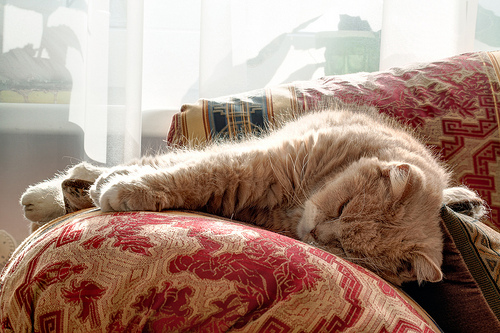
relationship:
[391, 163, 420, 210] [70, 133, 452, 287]
ear of cat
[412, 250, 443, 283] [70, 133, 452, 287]
left ear cat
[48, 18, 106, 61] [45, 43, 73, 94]
window has sunlight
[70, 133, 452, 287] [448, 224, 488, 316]
cat sleeping on pillow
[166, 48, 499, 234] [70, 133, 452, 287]
cushion has cat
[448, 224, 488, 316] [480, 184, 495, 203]
pillow in corner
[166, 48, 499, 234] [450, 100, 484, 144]
cushion has pattern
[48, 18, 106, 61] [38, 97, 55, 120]
window has item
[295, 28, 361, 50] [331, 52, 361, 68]
plant has seal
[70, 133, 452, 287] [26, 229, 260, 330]
cat napping on couch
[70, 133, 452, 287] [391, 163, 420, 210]
cat has ear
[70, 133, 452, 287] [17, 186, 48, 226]
cat has paw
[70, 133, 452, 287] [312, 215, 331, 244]
cat has nose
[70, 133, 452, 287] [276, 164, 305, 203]
cat has whiskers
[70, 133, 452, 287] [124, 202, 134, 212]
cat has claws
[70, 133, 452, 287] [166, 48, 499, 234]
cat on cushion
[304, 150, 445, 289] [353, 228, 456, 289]
head lying down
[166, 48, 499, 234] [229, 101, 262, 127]
cushion has stripe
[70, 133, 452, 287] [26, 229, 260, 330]
cat on couch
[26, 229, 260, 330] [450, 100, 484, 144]
couch has pattern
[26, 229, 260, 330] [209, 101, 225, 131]
couch has blue stripes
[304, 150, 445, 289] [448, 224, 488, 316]
head on pillow